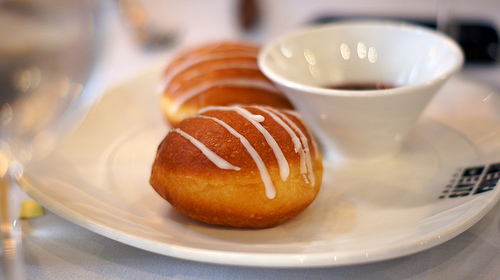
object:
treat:
[147, 101, 325, 233]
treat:
[155, 37, 300, 128]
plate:
[7, 54, 500, 272]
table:
[0, 14, 500, 280]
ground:
[0, 0, 500, 280]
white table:
[0, 16, 500, 280]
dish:
[7, 54, 500, 270]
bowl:
[252, 15, 467, 166]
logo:
[437, 159, 500, 201]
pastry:
[143, 101, 328, 231]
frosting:
[167, 99, 319, 200]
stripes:
[164, 103, 319, 202]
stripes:
[165, 74, 285, 114]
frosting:
[165, 74, 286, 112]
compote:
[317, 77, 397, 91]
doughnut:
[144, 100, 332, 230]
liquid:
[321, 77, 398, 90]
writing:
[437, 158, 498, 198]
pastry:
[159, 64, 297, 128]